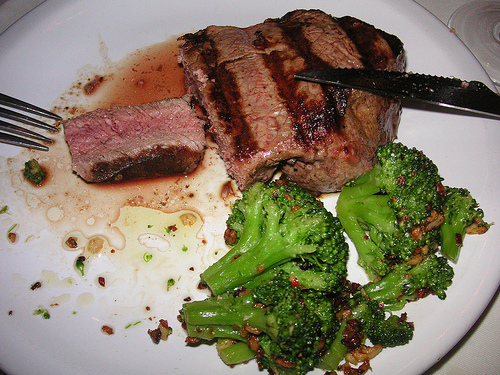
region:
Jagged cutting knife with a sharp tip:
[288, 53, 499, 125]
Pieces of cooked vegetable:
[175, 140, 497, 374]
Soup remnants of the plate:
[8, 69, 204, 254]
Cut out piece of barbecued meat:
[57, 86, 209, 186]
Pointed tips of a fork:
[0, 88, 65, 154]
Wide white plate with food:
[0, 0, 498, 373]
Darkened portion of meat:
[181, 25, 257, 166]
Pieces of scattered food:
[0, 202, 176, 347]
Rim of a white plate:
[416, 275, 496, 372]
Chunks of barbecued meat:
[57, 0, 414, 197]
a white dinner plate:
[5, 8, 496, 373]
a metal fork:
[0, 93, 60, 154]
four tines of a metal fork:
[3, 95, 61, 152]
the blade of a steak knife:
[299, 69, 499, 117]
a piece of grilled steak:
[65, 5, 407, 183]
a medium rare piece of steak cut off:
[67, 100, 199, 177]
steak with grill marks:
[177, 5, 407, 178]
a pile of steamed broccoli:
[179, 152, 480, 373]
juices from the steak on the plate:
[27, 38, 222, 260]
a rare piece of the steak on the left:
[65, 97, 206, 184]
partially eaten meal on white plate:
[0, 0, 499, 374]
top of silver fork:
[2, 89, 64, 148]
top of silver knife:
[294, 64, 499, 124]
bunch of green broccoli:
[177, 135, 492, 372]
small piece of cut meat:
[57, 91, 207, 189]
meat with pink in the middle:
[59, 91, 206, 188]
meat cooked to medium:
[57, 96, 214, 187]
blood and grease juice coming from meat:
[18, 1, 408, 250]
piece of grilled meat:
[176, 4, 407, 199]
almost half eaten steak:
[62, 5, 412, 190]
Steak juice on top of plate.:
[47, 192, 107, 256]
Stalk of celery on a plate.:
[233, 186, 327, 355]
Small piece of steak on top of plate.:
[58, 102, 200, 171]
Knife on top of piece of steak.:
[291, 64, 499, 121]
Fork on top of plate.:
[2, 85, 54, 152]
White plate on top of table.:
[6, 11, 490, 362]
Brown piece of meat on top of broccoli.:
[341, 316, 361, 354]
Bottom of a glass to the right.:
[445, 2, 497, 67]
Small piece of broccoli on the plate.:
[70, 255, 90, 283]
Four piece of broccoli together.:
[246, 160, 441, 337]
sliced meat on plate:
[60, 75, 217, 180]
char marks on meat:
[175, 21, 352, 178]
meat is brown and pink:
[37, 4, 372, 168]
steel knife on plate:
[315, 68, 497, 127]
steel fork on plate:
[2, 66, 44, 168]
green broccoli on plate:
[152, 141, 496, 358]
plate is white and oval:
[4, 0, 493, 357]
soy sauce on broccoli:
[193, 181, 491, 359]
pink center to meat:
[86, 112, 193, 164]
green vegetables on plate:
[208, 151, 463, 351]